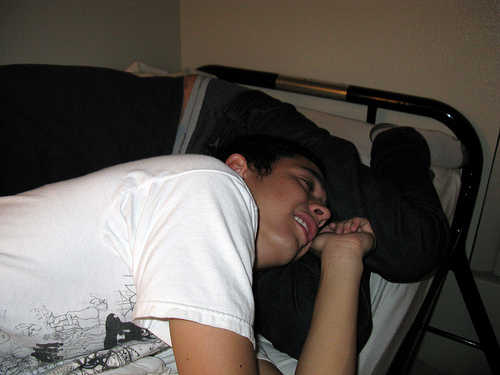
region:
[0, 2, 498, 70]
corner of two walls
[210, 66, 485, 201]
curved edge of headboard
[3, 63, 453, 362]
bent legs on bed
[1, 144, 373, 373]
person laying on their side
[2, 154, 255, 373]
white short sleeved shirt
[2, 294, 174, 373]
black design on shirt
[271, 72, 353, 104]
metal section of headboard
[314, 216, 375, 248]
bent fingers on hand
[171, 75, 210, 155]
elastic top of underwear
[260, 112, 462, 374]
white sheet on bed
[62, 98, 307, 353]
This is a bed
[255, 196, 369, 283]
This is a mouth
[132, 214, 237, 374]
This is an arm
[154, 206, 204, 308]
This is a tee shirt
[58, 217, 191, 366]
The shirt is white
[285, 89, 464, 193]
This is a bar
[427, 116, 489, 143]
The bar is black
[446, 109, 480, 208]
The bar is metal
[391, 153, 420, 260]
This is a sweatshirt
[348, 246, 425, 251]
The sweatshirt is black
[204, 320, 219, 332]
edge of a sleeve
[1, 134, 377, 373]
a man sleeping on a bed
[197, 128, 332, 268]
man with short black hair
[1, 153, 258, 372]
man wearing a white shirt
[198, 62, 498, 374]
black metal frame of a bed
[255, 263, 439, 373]
white sheets on a bed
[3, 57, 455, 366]
a man wearing black sleeping on a bed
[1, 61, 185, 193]
man wearing a black shirt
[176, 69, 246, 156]
man wearing gray underwear with a white border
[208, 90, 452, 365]
man wearing black pants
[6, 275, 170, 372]
a white and black drawing on a shirt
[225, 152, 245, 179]
the ear on the boy's head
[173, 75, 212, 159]
the elastic band on the boy's underwear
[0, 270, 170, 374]
the design on the front of the boy's shirt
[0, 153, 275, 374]
the boy's white short sleeved shirt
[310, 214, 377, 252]
the boy's left hand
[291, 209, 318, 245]
the mouth on the boy's face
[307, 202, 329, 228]
the nose on the boy's face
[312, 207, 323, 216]
the nostril in the boy's nose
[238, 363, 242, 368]
the beauty mark on the boy's arm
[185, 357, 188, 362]
the beauty mark on the boy's arm